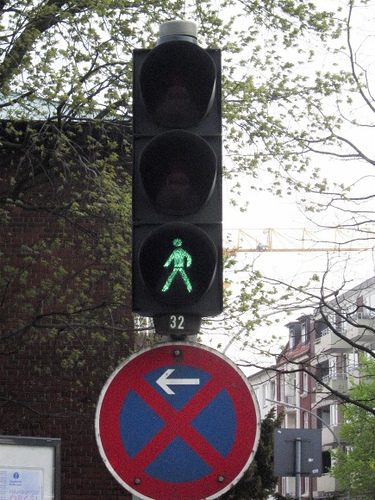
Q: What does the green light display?
A: Walking figure.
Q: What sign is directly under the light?
A: Red X sign.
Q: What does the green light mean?
A: Go.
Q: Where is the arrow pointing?
A: Left.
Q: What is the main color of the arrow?
A: White.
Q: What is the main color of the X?
A: Red.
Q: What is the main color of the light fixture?
A: Black.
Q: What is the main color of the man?
A: Green.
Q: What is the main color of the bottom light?
A: Green.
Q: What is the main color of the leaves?
A: Green.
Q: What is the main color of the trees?
A: Green.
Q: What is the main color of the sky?
A: White.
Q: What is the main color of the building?
A: Brown.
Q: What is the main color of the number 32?
A: White.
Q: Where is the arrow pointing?
A: Left.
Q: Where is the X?
A: On the sign.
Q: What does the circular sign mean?
A: No left turn.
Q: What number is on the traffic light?
A: 32.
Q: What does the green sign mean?
A: Walk.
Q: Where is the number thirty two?
A: Bottom of light.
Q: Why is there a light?
A: Pedestrians.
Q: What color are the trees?
A: Green.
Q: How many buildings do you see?
A: Four.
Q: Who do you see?
A: Nobody.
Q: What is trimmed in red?
A: A sign.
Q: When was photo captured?
A: Daytime.